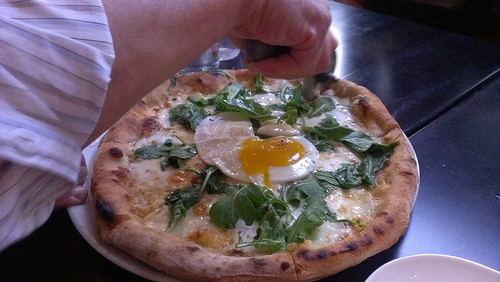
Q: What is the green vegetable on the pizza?
A: Spinach.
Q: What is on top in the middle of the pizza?
A: A sunny side up egg.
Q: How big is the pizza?
A: Big enough for one person.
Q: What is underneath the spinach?
A: Cheese.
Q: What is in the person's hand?
A: A pizza cutter.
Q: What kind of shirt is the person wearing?
A: A long sleeve button down shirt.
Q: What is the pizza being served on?
A: A white plate.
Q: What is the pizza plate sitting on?
A: A wooden table.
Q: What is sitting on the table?
A: The pizza on a plate.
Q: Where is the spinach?
A: On the pizza.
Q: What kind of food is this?
A: Pizza.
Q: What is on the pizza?
A: An egg.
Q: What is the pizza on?
A: A white plate.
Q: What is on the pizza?
A: Green vegetables.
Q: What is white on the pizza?
A: The cheese.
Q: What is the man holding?
A: A pizza cutter.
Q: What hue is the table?
A: Dark cherry brown.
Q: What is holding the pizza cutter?
A: The man's hand.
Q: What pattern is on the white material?
A: Pinstripes.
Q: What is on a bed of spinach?
A: A cooked egg.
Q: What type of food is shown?
A: Pizza.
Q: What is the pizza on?
A: Plate.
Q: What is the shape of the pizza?
A: Round.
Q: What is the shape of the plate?
A: Round.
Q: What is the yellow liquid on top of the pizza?
A: Egg yolk.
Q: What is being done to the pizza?
A: It is being cut.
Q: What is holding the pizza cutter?
A: Hand.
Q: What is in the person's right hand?
A: Pizza cutter.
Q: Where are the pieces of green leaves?
A: On the pizza.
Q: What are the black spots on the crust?
A: Burnt spots.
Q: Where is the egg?
A: In the middle of the pizza.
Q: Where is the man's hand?
A: Over the pizza.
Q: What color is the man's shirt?
A: White and blue.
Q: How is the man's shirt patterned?
A: Stripes.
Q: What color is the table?
A: Black.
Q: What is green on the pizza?
A: Basil.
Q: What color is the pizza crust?
A: Tan.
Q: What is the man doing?
A: Adding basil to the pizza.